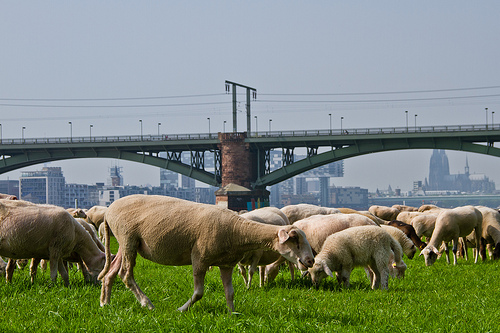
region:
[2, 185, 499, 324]
a herd of sheep in a green field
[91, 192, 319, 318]
sheep has been recently sheared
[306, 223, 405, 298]
sheep is unsheared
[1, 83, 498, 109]
overhead power cables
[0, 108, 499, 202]
a metal bridge with arched supports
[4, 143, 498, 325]
a city scene behind some sheep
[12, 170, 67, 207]
tall multi story building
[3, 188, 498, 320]
some sheep are grazing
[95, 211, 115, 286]
long skinny sheared sheep tail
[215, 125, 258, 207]
support for a bridge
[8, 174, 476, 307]
many animals in photo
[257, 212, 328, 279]
head of the animal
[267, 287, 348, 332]
grass under the animal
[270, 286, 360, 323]
green grass in photo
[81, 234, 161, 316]
back legs of the animal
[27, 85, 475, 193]
bridge in the photo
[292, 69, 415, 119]
wires above the bridge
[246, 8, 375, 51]
sky above the bridge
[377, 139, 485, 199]
buildings in the background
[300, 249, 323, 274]
nose of the animal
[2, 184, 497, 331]
sheep in green field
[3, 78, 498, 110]
powerlines over field of sheep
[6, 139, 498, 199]
cityscape beyond field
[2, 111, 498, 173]
bridge over field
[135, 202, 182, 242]
shorn skin of sheep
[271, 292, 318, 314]
blades of green grass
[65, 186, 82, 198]
window on side of city building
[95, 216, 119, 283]
sheep tail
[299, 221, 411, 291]
lamb grazing on grass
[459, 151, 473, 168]
steeple on building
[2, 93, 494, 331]
herd of sheep grazing near an urban scene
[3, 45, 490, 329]
sheep grazing near a bridge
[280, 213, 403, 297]
small lamb grazing near mother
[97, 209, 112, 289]
this sheep has a long tail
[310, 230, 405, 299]
small lamb is flufflier than the other sheep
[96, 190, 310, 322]
this sheep has been freshly shorn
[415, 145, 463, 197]
an out of focus skyscraper in the distance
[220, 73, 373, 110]
electrical lines running over top of a bridge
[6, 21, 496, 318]
cattle grazing in a field near a city